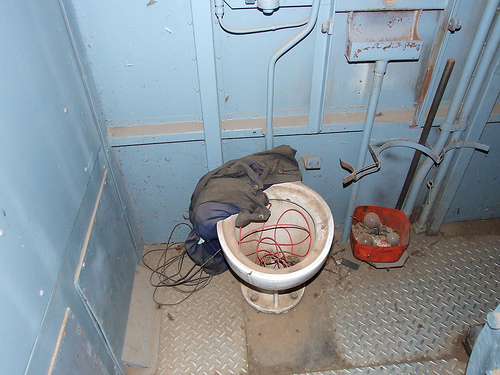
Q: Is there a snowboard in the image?
A: No, there are no snowboards.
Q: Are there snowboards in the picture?
A: No, there are no snowboards.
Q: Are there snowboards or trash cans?
A: No, there are no snowboards or trash cans.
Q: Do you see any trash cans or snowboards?
A: No, there are no snowboards or trash cans.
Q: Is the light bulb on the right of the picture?
A: Yes, the light bulb is on the right of the image.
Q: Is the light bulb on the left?
A: No, the light bulb is on the right of the image.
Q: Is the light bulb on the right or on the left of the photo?
A: The light bulb is on the right of the image.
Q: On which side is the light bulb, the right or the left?
A: The light bulb is on the right of the image.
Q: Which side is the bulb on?
A: The bulb is on the right of the image.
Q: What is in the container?
A: The light bulb is in the container.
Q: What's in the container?
A: The light bulb is in the container.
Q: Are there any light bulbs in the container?
A: Yes, there is a light bulb in the container.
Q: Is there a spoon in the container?
A: No, there is a light bulb in the container.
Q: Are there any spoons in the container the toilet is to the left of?
A: No, there is a light bulb in the container.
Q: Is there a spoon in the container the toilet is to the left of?
A: No, there is a light bulb in the container.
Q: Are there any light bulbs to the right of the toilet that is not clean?
A: Yes, there is a light bulb to the right of the toilet.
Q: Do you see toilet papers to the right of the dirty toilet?
A: No, there is a light bulb to the right of the toilet.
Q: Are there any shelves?
A: No, there are no shelves.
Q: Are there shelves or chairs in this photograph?
A: No, there are no shelves or chairs.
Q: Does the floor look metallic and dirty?
A: Yes, the floor is metallic and dirty.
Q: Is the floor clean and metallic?
A: No, the floor is metallic but dirty.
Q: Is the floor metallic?
A: Yes, the floor is metallic.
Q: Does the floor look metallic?
A: Yes, the floor is metallic.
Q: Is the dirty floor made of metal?
A: Yes, the floor is made of metal.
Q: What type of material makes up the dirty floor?
A: The floor is made of metal.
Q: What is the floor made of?
A: The floor is made of metal.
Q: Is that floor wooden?
A: No, the floor is metallic.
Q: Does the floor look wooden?
A: No, the floor is metallic.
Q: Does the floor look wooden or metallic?
A: The floor is metallic.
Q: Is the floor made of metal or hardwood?
A: The floor is made of metal.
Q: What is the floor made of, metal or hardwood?
A: The floor is made of metal.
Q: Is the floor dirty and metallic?
A: Yes, the floor is dirty and metallic.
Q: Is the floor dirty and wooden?
A: No, the floor is dirty but metallic.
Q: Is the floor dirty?
A: Yes, the floor is dirty.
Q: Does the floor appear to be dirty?
A: Yes, the floor is dirty.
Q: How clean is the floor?
A: The floor is dirty.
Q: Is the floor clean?
A: No, the floor is dirty.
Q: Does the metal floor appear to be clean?
A: No, the floor is dirty.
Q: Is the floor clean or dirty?
A: The floor is dirty.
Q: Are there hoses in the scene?
A: No, there are no hoses.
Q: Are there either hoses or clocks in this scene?
A: No, there are no hoses or clocks.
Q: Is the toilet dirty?
A: Yes, the toilet is dirty.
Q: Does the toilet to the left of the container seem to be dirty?
A: Yes, the toilet is dirty.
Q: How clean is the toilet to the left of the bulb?
A: The toilet is dirty.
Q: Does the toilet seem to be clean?
A: No, the toilet is dirty.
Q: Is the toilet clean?
A: No, the toilet is dirty.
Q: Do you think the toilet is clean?
A: No, the toilet is dirty.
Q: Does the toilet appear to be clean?
A: No, the toilet is dirty.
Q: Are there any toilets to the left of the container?
A: Yes, there is a toilet to the left of the container.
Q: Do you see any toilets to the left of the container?
A: Yes, there is a toilet to the left of the container.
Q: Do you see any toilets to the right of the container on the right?
A: No, the toilet is to the left of the container.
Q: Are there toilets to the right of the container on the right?
A: No, the toilet is to the left of the container.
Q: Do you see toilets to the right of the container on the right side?
A: No, the toilet is to the left of the container.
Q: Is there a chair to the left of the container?
A: No, there is a toilet to the left of the container.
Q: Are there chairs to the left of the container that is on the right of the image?
A: No, there is a toilet to the left of the container.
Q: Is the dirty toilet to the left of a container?
A: Yes, the toilet is to the left of a container.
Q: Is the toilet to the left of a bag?
A: No, the toilet is to the left of a container.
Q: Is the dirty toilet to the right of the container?
A: No, the toilet is to the left of the container.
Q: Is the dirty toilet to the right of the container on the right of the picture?
A: No, the toilet is to the left of the container.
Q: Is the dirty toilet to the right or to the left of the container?
A: The toilet is to the left of the container.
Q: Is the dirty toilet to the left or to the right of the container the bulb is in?
A: The toilet is to the left of the container.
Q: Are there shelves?
A: No, there are no shelves.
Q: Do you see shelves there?
A: No, there are no shelves.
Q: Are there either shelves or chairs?
A: No, there are no shelves or chairs.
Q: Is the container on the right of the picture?
A: Yes, the container is on the right of the image.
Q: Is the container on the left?
A: No, the container is on the right of the image.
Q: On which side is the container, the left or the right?
A: The container is on the right of the image.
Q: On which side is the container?
A: The container is on the right of the image.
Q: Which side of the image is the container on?
A: The container is on the right of the image.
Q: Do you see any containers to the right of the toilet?
A: Yes, there is a container to the right of the toilet.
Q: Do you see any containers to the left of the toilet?
A: No, the container is to the right of the toilet.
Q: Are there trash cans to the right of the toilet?
A: No, there is a container to the right of the toilet.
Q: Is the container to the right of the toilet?
A: Yes, the container is to the right of the toilet.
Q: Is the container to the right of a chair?
A: No, the container is to the right of the toilet.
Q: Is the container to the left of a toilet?
A: No, the container is to the right of a toilet.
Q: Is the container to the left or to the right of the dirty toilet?
A: The container is to the right of the toilet.